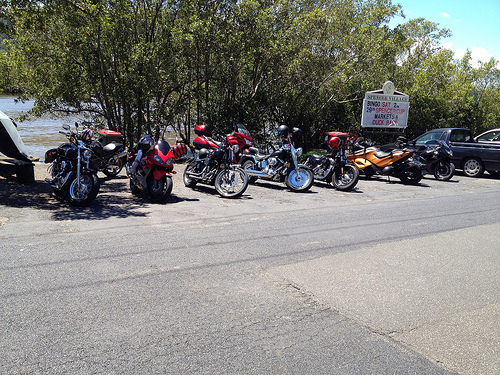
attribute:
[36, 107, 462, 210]
motorcycles — together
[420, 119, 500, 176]
truck — blue, black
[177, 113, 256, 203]
motorcycle — red, black, bright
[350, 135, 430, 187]
motorcycle — orange, golden cafe, cafe, red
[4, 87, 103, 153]
water — murky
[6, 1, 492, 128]
trees — green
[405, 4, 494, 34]
sky — blue, aqua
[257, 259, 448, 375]
pavement — crack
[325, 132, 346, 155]
helmet — red, round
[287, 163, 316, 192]
wheel — shiny chrome, silvertone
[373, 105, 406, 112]
letters — red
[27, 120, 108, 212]
bike — black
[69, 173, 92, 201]
hubcap — silvertone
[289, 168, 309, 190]
hubcap — fancy